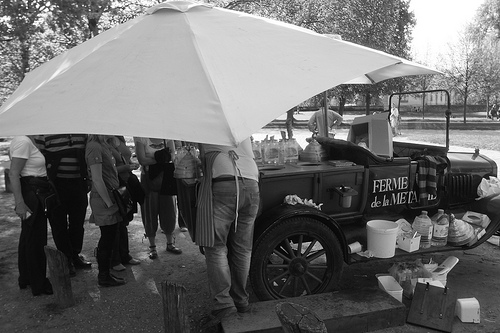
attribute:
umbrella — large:
[19, 9, 429, 153]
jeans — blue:
[199, 181, 279, 316]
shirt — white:
[206, 137, 287, 193]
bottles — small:
[256, 133, 314, 163]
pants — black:
[95, 222, 120, 279]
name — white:
[364, 172, 408, 207]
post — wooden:
[159, 278, 191, 330]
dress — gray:
[80, 133, 148, 291]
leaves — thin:
[8, 34, 40, 57]